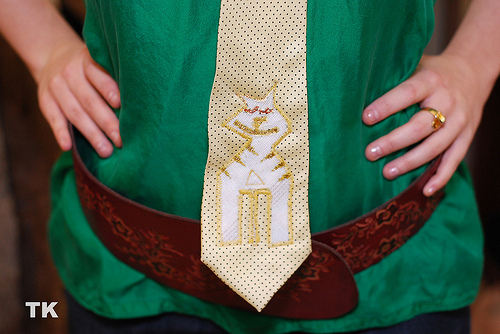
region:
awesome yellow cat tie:
[209, 78, 317, 255]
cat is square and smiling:
[199, 70, 302, 267]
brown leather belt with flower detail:
[49, 136, 481, 324]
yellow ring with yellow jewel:
[422, 98, 465, 150]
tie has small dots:
[216, 15, 319, 88]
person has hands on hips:
[31, 40, 478, 210]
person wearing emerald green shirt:
[59, 11, 487, 332]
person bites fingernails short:
[38, 78, 149, 185]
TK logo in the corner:
[21, 281, 78, 324]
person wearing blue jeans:
[59, 293, 484, 331]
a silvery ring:
[420, 104, 444, 128]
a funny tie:
[196, 2, 313, 310]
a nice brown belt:
[48, 152, 452, 317]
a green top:
[43, 4, 484, 321]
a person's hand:
[0, 0, 126, 154]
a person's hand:
[366, 5, 498, 211]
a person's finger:
[361, 77, 428, 124]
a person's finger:
[366, 106, 441, 160]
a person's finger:
[423, 137, 473, 198]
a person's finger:
[81, 56, 124, 104]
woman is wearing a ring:
[365, 78, 481, 187]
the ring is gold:
[410, 87, 457, 154]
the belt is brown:
[36, 99, 438, 331]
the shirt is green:
[66, 0, 452, 328]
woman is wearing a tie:
[185, 3, 337, 329]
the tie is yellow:
[198, 3, 344, 330]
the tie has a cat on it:
[171, 20, 376, 320]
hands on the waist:
[33, 5, 478, 331]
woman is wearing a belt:
[46, 105, 456, 332]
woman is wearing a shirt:
[63, 0, 445, 302]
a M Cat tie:
[194, 60, 368, 331]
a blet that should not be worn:
[89, 163, 491, 274]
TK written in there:
[12, 284, 74, 326]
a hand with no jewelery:
[39, 41, 159, 166]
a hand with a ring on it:
[359, 60, 492, 185]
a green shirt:
[305, 28, 387, 227]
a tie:
[202, 12, 332, 287]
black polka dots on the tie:
[225, 18, 275, 68]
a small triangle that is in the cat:
[241, 167, 298, 199]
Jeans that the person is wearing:
[44, 250, 197, 331]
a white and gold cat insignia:
[212, 80, 299, 264]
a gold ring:
[408, 88, 453, 138]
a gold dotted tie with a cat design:
[198, 2, 325, 313]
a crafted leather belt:
[50, 133, 498, 320]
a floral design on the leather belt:
[325, 194, 430, 266]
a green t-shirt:
[51, 3, 491, 322]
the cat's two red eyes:
[240, 98, 283, 117]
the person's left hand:
[355, 41, 492, 218]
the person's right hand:
[11, 13, 146, 189]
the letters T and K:
[18, 292, 65, 325]